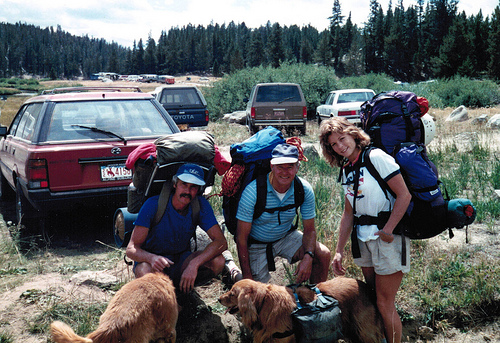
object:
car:
[316, 88, 378, 125]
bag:
[289, 282, 348, 343]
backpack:
[348, 91, 482, 242]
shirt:
[235, 177, 316, 244]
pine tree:
[143, 30, 159, 73]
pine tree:
[133, 37, 144, 75]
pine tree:
[120, 47, 135, 75]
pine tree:
[101, 39, 119, 73]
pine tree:
[267, 19, 289, 69]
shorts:
[353, 234, 411, 276]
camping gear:
[114, 130, 230, 248]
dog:
[215, 276, 381, 342]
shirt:
[338, 150, 402, 243]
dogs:
[49, 272, 381, 342]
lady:
[313, 117, 411, 343]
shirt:
[133, 193, 217, 270]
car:
[0, 93, 187, 248]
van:
[248, 83, 307, 133]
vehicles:
[155, 83, 378, 135]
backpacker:
[233, 144, 333, 286]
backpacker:
[125, 162, 229, 292]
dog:
[48, 273, 177, 341]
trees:
[289, 0, 498, 78]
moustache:
[179, 193, 192, 200]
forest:
[2, 1, 500, 81]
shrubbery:
[200, 61, 496, 119]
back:
[277, 272, 339, 304]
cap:
[177, 163, 207, 186]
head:
[173, 163, 205, 205]